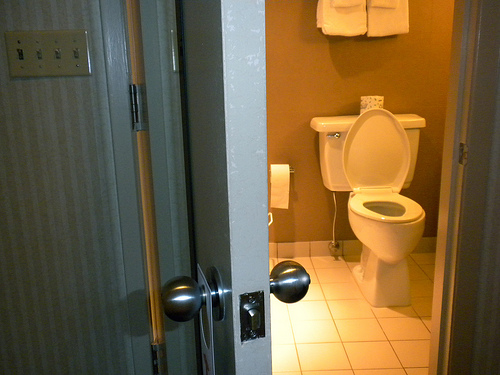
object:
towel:
[314, 2, 368, 39]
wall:
[265, 1, 455, 257]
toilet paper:
[359, 93, 383, 117]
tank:
[310, 113, 427, 191]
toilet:
[309, 112, 426, 307]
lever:
[328, 133, 342, 140]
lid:
[341, 107, 413, 195]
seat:
[347, 190, 424, 224]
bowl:
[346, 192, 427, 264]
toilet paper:
[269, 162, 292, 212]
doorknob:
[272, 260, 311, 304]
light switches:
[71, 47, 79, 57]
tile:
[297, 341, 354, 373]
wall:
[0, 5, 199, 373]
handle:
[158, 265, 226, 322]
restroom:
[263, 0, 456, 373]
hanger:
[196, 262, 213, 374]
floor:
[268, 252, 438, 373]